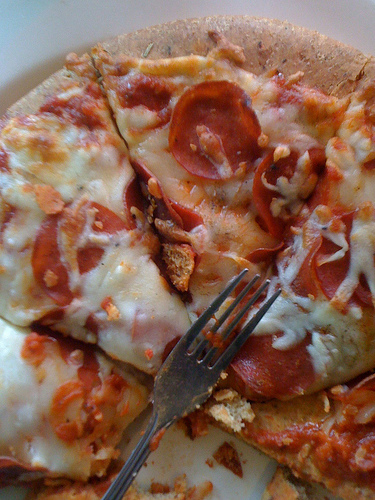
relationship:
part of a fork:
[213, 290, 280, 369] [134, 268, 284, 443]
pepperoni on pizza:
[32, 76, 372, 400] [0, 15, 373, 498]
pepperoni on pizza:
[229, 299, 319, 400] [0, 15, 373, 498]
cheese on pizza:
[84, 248, 182, 362] [0, 15, 373, 498]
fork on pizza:
[94, 266, 285, 498] [0, 15, 373, 498]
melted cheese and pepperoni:
[16, 175, 184, 398] [30, 199, 126, 301]